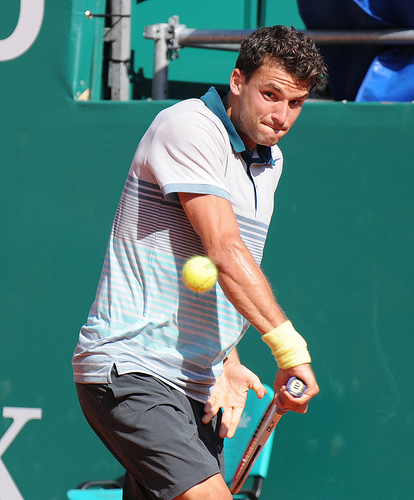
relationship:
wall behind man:
[5, 117, 101, 231] [79, 27, 354, 333]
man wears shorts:
[61, 16, 331, 498] [68, 348, 243, 498]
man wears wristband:
[61, 16, 331, 498] [259, 320, 311, 369]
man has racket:
[61, 16, 331, 498] [223, 368, 313, 497]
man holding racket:
[72, 24, 326, 500] [229, 371, 315, 492]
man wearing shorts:
[72, 24, 326, 500] [82, 385, 232, 494]